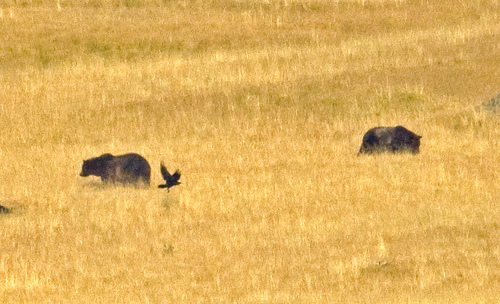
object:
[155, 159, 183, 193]
bird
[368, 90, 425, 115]
green patch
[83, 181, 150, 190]
shadow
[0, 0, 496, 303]
field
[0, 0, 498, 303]
grass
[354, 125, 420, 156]
bear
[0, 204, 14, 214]
creatures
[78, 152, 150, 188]
bear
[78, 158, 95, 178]
head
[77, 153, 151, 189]
bison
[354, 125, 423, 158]
left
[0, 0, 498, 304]
wild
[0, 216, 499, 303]
part